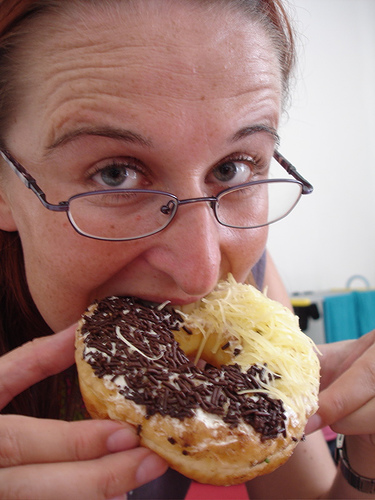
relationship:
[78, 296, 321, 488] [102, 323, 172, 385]
donut has sprinkles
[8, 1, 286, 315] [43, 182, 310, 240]
girl wears glasses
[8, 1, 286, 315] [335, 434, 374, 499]
girl has band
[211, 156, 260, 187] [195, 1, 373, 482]
eye on right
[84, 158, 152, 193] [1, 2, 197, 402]
eye on left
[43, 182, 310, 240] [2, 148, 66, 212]
glasses have wire frame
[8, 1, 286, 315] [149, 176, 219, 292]
woman has nose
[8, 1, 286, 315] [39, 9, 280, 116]
woman has forehead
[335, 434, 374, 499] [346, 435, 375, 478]
band on wrist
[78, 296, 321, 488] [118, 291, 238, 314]
donut being eaten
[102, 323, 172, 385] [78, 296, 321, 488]
sprinkles are on donut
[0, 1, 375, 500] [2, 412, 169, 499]
girl has fingers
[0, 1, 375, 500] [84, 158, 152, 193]
girl has an eye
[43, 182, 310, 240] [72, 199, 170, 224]
glasses have a lens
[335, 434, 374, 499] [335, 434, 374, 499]
band has a band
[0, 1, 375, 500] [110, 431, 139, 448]
girl has fingernail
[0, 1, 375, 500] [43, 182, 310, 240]
girl has glasses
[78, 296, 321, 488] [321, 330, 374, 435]
donut in hand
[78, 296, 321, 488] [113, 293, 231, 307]
donut in mouth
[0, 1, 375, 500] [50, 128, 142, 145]
girl has eyebrow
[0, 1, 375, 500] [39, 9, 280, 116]
girl has forehead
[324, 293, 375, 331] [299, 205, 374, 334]
bag in background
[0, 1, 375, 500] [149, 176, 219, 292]
girl has nose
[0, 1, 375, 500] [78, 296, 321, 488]
girl eating donut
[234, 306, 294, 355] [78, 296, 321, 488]
frosting on donut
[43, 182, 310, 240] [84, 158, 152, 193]
glasses cover eye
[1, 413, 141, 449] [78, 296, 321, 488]
finger grasping donut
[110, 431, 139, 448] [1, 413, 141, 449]
fingernail on finger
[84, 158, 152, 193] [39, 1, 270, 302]
eye are on face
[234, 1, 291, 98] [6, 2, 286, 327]
hair on head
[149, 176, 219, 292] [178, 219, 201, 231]
nose has freckles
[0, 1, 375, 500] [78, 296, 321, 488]
girl has donut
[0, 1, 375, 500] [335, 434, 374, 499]
girl has band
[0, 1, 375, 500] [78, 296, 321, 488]
girl biting donut